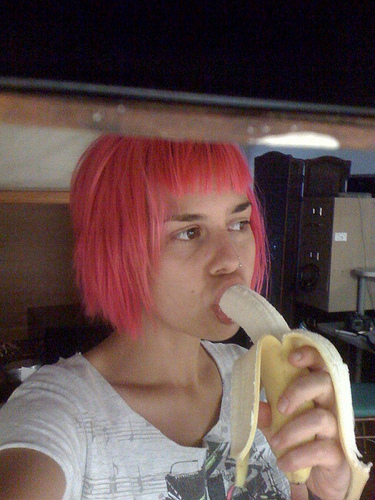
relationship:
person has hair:
[9, 126, 371, 498] [55, 130, 278, 335]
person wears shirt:
[9, 126, 371, 498] [3, 339, 286, 497]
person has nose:
[9, 126, 371, 498] [204, 227, 243, 273]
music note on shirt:
[97, 419, 117, 444] [3, 339, 286, 497]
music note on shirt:
[124, 411, 134, 445] [3, 339, 286, 497]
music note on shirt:
[105, 457, 121, 495] [3, 339, 286, 497]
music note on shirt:
[131, 465, 143, 496] [3, 339, 286, 497]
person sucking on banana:
[0, 128, 353, 499] [212, 280, 374, 496]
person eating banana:
[0, 128, 353, 499] [212, 280, 374, 496]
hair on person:
[67, 133, 274, 340] [0, 128, 353, 499]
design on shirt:
[159, 433, 290, 498] [0, 339, 294, 498]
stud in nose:
[236, 259, 244, 269] [201, 221, 241, 273]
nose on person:
[204, 218, 241, 273] [9, 126, 371, 498]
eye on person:
[223, 217, 249, 232] [9, 126, 371, 498]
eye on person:
[169, 225, 201, 242] [9, 126, 371, 498]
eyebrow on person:
[225, 200, 253, 214] [9, 126, 371, 498]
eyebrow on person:
[160, 210, 209, 222] [9, 126, 371, 498]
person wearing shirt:
[9, 126, 371, 498] [3, 339, 286, 497]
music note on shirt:
[125, 419, 133, 440] [3, 339, 286, 497]